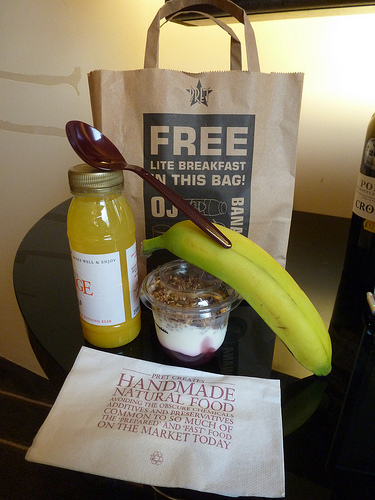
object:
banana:
[141, 218, 332, 377]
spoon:
[67, 121, 233, 248]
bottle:
[67, 164, 142, 347]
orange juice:
[67, 198, 141, 350]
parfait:
[138, 259, 245, 361]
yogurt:
[154, 316, 226, 355]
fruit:
[164, 320, 219, 335]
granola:
[151, 272, 228, 325]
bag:
[88, 1, 304, 287]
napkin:
[25, 346, 286, 499]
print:
[95, 367, 236, 452]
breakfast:
[68, 166, 332, 376]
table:
[13, 190, 352, 404]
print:
[142, 113, 251, 238]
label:
[69, 243, 146, 328]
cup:
[138, 257, 246, 365]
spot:
[276, 327, 286, 333]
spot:
[275, 315, 280, 320]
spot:
[259, 303, 264, 308]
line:
[2, 390, 51, 413]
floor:
[1, 371, 28, 499]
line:
[1, 437, 28, 450]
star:
[185, 79, 213, 106]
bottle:
[343, 114, 374, 257]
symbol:
[148, 451, 164, 466]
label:
[352, 172, 374, 233]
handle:
[145, 2, 258, 73]